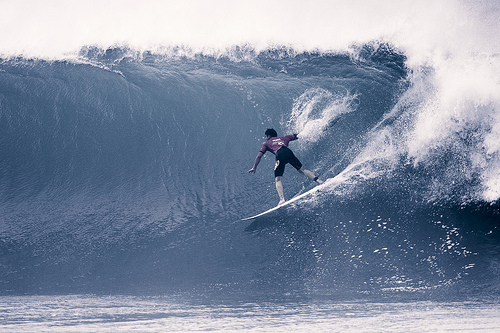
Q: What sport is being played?
A: Surfing.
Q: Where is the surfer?
A: In the ocean.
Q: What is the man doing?
A: Surfing.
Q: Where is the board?
A: Under the man.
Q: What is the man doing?
A: Surfing.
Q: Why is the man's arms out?
A: Balancing.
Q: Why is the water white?
A: Crashing waves.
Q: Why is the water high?
A: Waves.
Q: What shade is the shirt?
A: Purple.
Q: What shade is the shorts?
A: Black.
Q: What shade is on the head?
A: Black.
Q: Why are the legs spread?
A: Balancing.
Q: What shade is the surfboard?
A: White.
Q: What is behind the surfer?
A: Wave.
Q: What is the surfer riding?
A: Wave.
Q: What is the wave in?
A: Ocean.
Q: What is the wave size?
A: Large.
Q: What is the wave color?
A: White.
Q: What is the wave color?
A: Blue.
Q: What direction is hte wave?
A: Vertical.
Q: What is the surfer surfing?
A: Wave.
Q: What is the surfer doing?
A: Surfer sticking his hand in wave wall.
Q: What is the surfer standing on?
A: Surfer standing on surfboard.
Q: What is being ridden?
A: White foam of wave being ridden.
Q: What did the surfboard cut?
A: Path surfboard cut in wave.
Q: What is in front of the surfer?
A: Calm sea in front of wave.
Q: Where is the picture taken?
A: The ocean.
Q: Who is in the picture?
A: A man.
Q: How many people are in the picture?
A: One.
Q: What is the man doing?
A: Surfing.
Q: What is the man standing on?
A: Surfboard.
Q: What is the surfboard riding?
A: Wave.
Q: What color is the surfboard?
A: White.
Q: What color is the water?
A: Blue.